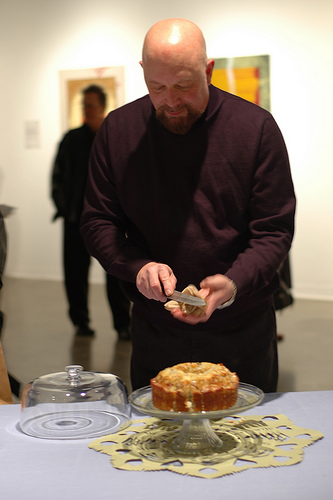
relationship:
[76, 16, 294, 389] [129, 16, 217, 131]
man has head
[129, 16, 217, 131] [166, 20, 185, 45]
head has spot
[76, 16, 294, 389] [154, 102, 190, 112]
man has mustache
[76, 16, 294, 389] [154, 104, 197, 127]
man has moustache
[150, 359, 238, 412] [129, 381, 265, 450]
cake on server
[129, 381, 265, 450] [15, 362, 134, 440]
server has lid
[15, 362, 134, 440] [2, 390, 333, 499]
lid on table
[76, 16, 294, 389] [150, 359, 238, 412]
man cutting cake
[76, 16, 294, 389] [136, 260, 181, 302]
man has hand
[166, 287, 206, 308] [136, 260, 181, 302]
knife in hand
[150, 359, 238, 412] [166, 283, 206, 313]
cake has slice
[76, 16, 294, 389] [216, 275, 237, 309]
man wearing watch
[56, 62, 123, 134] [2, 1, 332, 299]
painting on wall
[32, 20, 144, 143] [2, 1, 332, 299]
light on wall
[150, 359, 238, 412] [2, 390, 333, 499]
cake on table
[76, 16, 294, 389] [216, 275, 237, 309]
man wears watch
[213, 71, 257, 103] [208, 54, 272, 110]
picture has frame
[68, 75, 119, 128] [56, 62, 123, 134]
painting has frame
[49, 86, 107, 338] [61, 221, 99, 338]
man has leg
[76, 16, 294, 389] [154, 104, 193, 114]
man has moustache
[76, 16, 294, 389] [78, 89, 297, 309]
man wearing shirt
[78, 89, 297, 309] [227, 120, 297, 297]
shirt has sleeve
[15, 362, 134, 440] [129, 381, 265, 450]
lid next to server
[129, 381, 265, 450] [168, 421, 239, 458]
server has pedestal